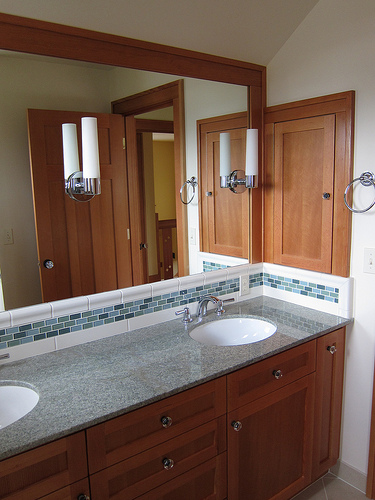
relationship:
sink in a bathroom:
[187, 313, 274, 348] [3, 0, 372, 496]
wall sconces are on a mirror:
[51, 109, 269, 199] [5, 3, 371, 284]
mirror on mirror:
[5, 3, 371, 284] [0, 51, 250, 284]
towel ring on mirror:
[337, 175, 374, 211] [0, 51, 250, 284]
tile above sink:
[8, 264, 358, 344] [187, 313, 274, 348]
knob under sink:
[261, 362, 293, 383] [187, 313, 274, 348]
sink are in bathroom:
[187, 313, 274, 348] [3, 0, 372, 496]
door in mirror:
[20, 105, 152, 301] [5, 3, 371, 284]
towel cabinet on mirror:
[257, 114, 336, 274] [0, 51, 250, 284]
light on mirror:
[226, 129, 264, 192] [5, 3, 371, 284]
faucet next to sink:
[174, 289, 237, 329] [187, 313, 274, 348]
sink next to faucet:
[187, 313, 274, 348] [174, 289, 237, 329]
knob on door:
[261, 362, 293, 383] [20, 105, 152, 301]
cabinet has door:
[257, 114, 336, 274] [20, 105, 152, 301]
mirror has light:
[5, 3, 371, 284] [226, 129, 264, 192]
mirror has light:
[5, 3, 371, 284] [58, 113, 105, 199]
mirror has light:
[0, 51, 250, 284] [226, 129, 264, 192]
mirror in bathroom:
[5, 3, 371, 284] [3, 0, 372, 496]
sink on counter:
[192, 313, 274, 348] [0, 292, 349, 459]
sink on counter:
[0, 375, 40, 429] [0, 292, 349, 459]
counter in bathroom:
[0, 292, 349, 459] [3, 0, 372, 496]